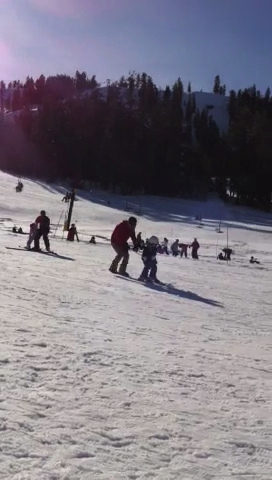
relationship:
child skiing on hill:
[139, 235, 161, 283] [0, 165, 271, 479]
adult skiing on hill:
[107, 213, 140, 276] [0, 165, 271, 479]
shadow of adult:
[113, 183, 246, 230] [107, 213, 140, 276]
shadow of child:
[113, 183, 246, 230] [138, 223, 160, 285]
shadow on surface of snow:
[113, 183, 246, 230] [0, 171, 270, 479]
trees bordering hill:
[91, 96, 218, 170] [0, 165, 271, 479]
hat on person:
[124, 213, 144, 226] [100, 203, 154, 264]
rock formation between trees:
[5, 83, 231, 184] [3, 69, 271, 212]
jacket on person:
[110, 219, 136, 248] [108, 214, 140, 279]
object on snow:
[88, 232, 97, 245] [0, 171, 270, 479]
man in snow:
[33, 208, 51, 251] [0, 171, 270, 479]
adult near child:
[109, 215, 138, 276] [137, 234, 163, 264]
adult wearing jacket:
[109, 215, 138, 276] [110, 219, 135, 245]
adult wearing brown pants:
[109, 215, 138, 276] [107, 239, 130, 277]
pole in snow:
[60, 183, 80, 233] [0, 171, 270, 479]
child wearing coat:
[142, 233, 159, 283] [141, 244, 157, 264]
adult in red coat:
[109, 215, 138, 276] [109, 217, 141, 246]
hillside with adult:
[1, 84, 271, 478] [109, 215, 138, 276]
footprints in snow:
[97, 426, 173, 448] [0, 171, 270, 479]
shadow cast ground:
[32, 179, 272, 237] [3, 181, 36, 217]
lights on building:
[160, 125, 247, 230] [110, 43, 252, 203]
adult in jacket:
[109, 215, 138, 276] [110, 219, 136, 248]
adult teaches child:
[109, 215, 138, 276] [139, 232, 159, 279]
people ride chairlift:
[11, 170, 40, 202] [9, 162, 47, 214]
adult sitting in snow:
[109, 215, 138, 276] [194, 268, 245, 332]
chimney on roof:
[117, 78, 129, 87] [64, 86, 194, 117]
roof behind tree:
[64, 86, 194, 117] [92, 77, 178, 122]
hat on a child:
[147, 235, 158, 244] [136, 232, 167, 289]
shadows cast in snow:
[109, 271, 223, 309] [144, 296, 178, 329]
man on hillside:
[18, 200, 64, 270] [34, 183, 93, 212]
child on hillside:
[23, 216, 46, 256] [34, 183, 93, 212]